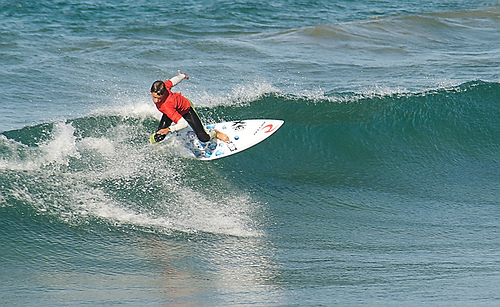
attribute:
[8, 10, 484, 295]
water — ocean, green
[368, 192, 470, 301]
water — calm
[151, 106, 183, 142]
arm — man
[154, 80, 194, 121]
shirt — man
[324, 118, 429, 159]
wave — green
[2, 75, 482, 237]
wave — crashing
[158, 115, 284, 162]
surfboard — white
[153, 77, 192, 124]
shirt — red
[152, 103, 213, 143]
wetsuit pants — black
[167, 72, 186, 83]
sleeve — white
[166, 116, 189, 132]
sleeve — white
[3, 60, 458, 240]
spray — white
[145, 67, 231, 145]
boy — surfing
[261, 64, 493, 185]
wave — about to crash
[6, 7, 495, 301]
ocean — choppy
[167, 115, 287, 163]
surfboard — white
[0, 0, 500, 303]
water — green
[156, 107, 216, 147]
pants — black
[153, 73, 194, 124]
tee shirt — red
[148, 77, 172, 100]
hair — brown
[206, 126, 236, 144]
foot — bare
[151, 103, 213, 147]
pants — black